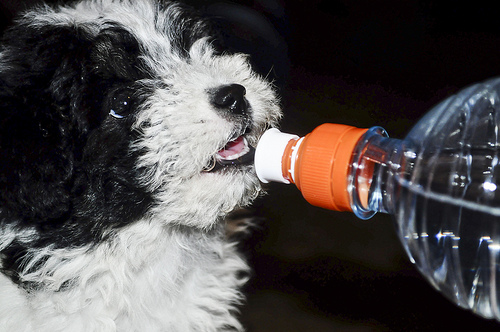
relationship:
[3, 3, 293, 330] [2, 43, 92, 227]
dog has ear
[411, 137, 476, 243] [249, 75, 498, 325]
water in bottle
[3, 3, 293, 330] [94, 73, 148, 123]
dog has eye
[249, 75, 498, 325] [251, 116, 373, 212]
bottle has top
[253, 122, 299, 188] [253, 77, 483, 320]
nozzle of water bottle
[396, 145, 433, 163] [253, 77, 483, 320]
light on water bottle